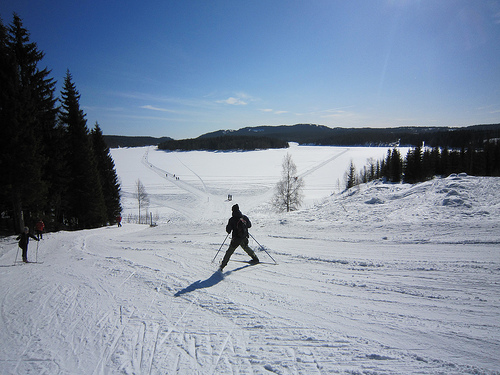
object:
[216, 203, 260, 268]
man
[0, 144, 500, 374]
snow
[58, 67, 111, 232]
trees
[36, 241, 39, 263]
ski poles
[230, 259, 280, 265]
skis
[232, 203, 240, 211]
cap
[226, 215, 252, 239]
jacket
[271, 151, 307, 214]
tree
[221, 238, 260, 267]
trousers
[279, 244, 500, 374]
track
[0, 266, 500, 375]
ground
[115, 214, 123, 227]
people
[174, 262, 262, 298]
shadow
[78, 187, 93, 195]
leaves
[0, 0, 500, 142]
sky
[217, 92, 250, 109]
clouds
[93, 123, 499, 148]
mountains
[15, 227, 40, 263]
person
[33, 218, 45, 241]
skier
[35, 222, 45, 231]
jacket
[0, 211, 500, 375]
slope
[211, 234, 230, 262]
stick